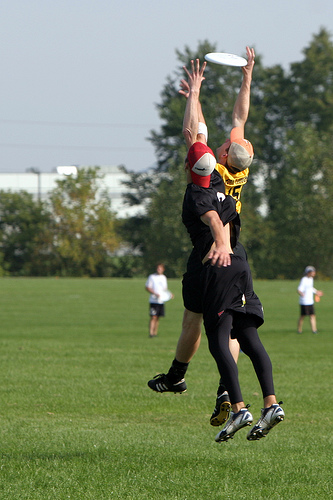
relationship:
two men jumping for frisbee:
[161, 42, 278, 393] [204, 51, 246, 67]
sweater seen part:
[181, 199, 265, 321] [188, 211, 196, 221]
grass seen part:
[4, 282, 332, 499] [132, 457, 141, 466]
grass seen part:
[4, 282, 329, 499] [148, 474, 157, 487]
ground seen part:
[3, 285, 332, 498] [58, 379, 91, 405]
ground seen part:
[3, 285, 332, 498] [146, 425, 170, 449]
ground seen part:
[112, 419, 140, 441] [115, 416, 144, 449]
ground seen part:
[3, 285, 332, 498] [165, 463, 181, 478]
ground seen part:
[3, 285, 332, 498] [115, 427, 129, 447]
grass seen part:
[4, 282, 329, 499] [138, 456, 161, 477]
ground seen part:
[3, 285, 332, 498] [141, 446, 150, 458]